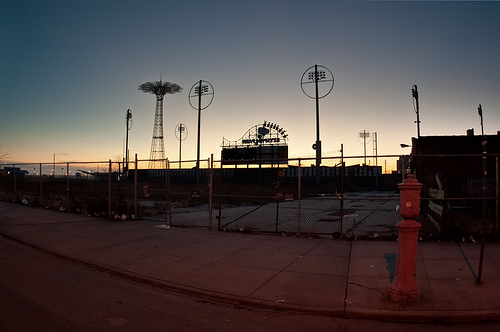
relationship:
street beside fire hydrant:
[22, 253, 492, 330] [381, 162, 430, 306]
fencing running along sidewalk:
[88, 171, 436, 245] [71, 221, 412, 318]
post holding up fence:
[294, 157, 303, 237] [1, 150, 493, 244]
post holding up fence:
[205, 151, 217, 229] [1, 150, 493, 244]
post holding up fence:
[131, 153, 138, 221] [1, 150, 493, 244]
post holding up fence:
[107, 159, 112, 217] [1, 150, 493, 244]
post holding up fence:
[64, 160, 71, 214] [1, 150, 493, 244]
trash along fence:
[12, 194, 137, 221] [1, 150, 493, 244]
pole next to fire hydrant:
[458, 100, 490, 301] [385, 168, 428, 290]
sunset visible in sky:
[17, 108, 485, 179] [94, 133, 216, 184]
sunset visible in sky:
[9, 85, 484, 172] [0, 1, 496, 165]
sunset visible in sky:
[4, 144, 399, 181] [3, 3, 483, 178]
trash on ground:
[1, 195, 137, 221] [9, 186, 484, 318]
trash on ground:
[417, 172, 494, 274] [9, 186, 484, 318]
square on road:
[281, 245, 354, 277] [0, 200, 500, 332]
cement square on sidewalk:
[185, 259, 282, 296] [34, 222, 371, 287]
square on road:
[0, 0, 500, 332] [0, 200, 500, 332]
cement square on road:
[80, 242, 154, 267] [0, 200, 500, 332]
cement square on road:
[165, 240, 245, 261] [0, 200, 500, 332]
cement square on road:
[223, 247, 304, 269] [0, 200, 500, 332]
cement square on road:
[348, 237, 424, 261] [0, 200, 500, 332]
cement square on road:
[432, 272, 499, 306] [0, 200, 500, 332]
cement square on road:
[227, 244, 307, 298] [0, 200, 500, 332]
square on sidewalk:
[423, 271, 498, 318] [1, 198, 495, 327]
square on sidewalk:
[222, 245, 302, 270] [6, 200, 499, 306]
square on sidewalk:
[122, 248, 216, 280] [6, 200, 499, 306]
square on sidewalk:
[353, 234, 422, 257] [6, 200, 499, 306]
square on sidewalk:
[0, 0, 500, 332] [6, 200, 499, 306]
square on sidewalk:
[431, 276, 489, 310] [6, 200, 499, 306]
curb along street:
[1, 231, 498, 331] [1, 234, 498, 331]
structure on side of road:
[390, 170, 424, 304] [4, 251, 125, 323]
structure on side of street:
[388, 173, 423, 303] [26, 275, 178, 320]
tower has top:
[133, 71, 182, 208] [135, 74, 182, 102]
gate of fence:
[133, 155, 217, 231] [1, 150, 493, 244]